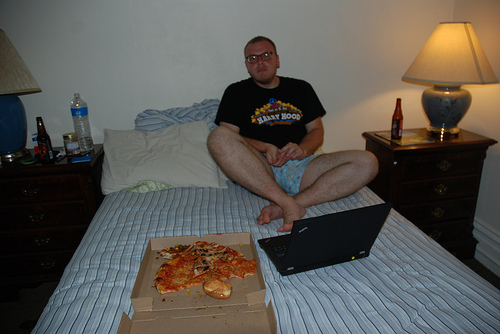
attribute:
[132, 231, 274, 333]
box — brown, cardboard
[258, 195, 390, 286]
laptop — black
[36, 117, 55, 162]
bottle — brown, glass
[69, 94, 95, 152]
water bottle — clear, plastic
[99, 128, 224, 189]
pillow — white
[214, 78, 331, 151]
shirt — black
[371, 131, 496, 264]
nightstand — brown, small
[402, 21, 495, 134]
lamp — blue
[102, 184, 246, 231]
sheet — blue, gray, white